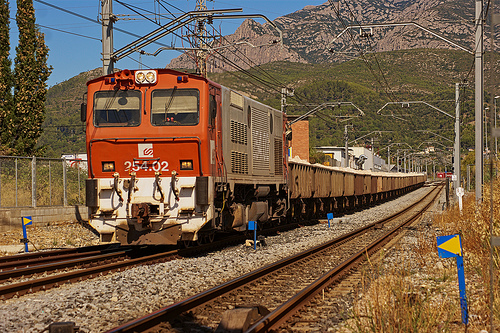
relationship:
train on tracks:
[68, 58, 444, 246] [6, 167, 449, 317]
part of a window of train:
[154, 91, 192, 122] [80, 63, 430, 255]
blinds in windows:
[95, 91, 200, 116] [89, 83, 206, 134]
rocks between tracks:
[15, 173, 431, 331] [6, 162, 444, 329]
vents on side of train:
[224, 120, 254, 174] [80, 63, 430, 255]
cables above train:
[2, 0, 492, 150] [80, 63, 430, 255]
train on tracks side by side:
[80, 63, 430, 255] [262, 103, 445, 240]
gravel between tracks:
[3, 185, 441, 330] [2, 234, 143, 306]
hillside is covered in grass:
[306, 56, 496, 171] [39, 51, 496, 160]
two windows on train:
[90, 82, 204, 134] [80, 63, 430, 255]